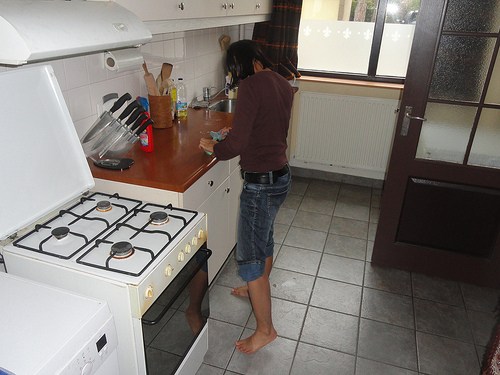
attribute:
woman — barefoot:
[198, 38, 296, 354]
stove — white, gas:
[2, 191, 203, 288]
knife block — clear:
[76, 109, 139, 166]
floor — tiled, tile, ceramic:
[192, 174, 499, 374]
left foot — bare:
[234, 327, 278, 356]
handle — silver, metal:
[397, 104, 427, 138]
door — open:
[370, 1, 498, 291]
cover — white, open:
[0, 63, 94, 240]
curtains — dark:
[249, 0, 305, 94]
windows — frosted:
[414, 1, 499, 174]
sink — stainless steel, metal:
[207, 96, 237, 115]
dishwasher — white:
[48, 314, 123, 374]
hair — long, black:
[224, 37, 275, 86]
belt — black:
[237, 163, 288, 183]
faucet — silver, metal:
[205, 83, 232, 103]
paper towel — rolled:
[103, 52, 117, 72]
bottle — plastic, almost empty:
[174, 77, 188, 121]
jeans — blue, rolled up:
[234, 169, 290, 283]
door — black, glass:
[142, 239, 210, 374]